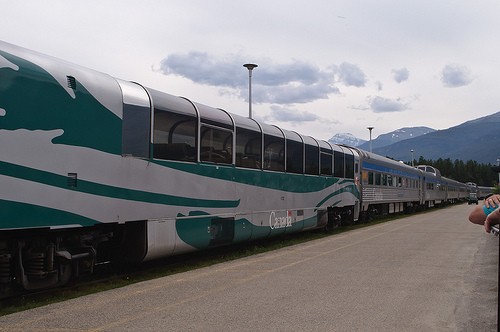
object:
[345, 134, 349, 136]
snow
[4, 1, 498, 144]
sky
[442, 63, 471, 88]
clouds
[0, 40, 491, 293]
train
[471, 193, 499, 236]
passengers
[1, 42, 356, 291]
car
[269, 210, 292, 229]
text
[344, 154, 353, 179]
windows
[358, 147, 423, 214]
cars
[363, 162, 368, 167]
blue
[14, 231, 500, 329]
platform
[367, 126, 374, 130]
lights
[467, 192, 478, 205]
cart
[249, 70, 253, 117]
pole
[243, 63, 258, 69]
light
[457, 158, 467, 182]
trees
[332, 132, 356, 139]
mountain top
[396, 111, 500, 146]
mountains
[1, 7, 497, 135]
background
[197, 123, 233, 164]
window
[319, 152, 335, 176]
window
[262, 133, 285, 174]
window